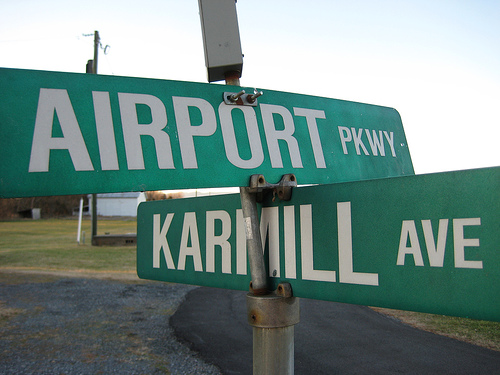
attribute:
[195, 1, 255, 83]
box — metal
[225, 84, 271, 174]
letter — white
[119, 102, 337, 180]
sign — green, white, street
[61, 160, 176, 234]
building — white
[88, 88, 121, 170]
letter — white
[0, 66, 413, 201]
sign — green, white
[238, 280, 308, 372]
pole — metal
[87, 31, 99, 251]
pole — wood, high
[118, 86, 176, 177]
letter — white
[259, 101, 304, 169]
letter — white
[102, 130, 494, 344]
sign — green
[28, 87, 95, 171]
letter a — white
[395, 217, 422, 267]
letter a — white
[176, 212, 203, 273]
letter a — white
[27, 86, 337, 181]
lettering — white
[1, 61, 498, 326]
signs — street, green, white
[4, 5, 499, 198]
sky — muted blue, white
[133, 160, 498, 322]
sign — green, white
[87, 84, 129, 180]
letter — white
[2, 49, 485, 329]
sign — green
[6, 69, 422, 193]
background — green